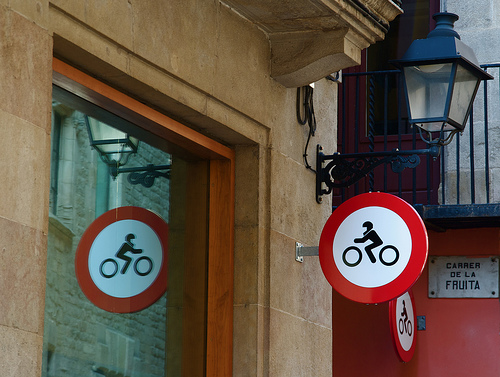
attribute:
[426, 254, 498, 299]
placard — white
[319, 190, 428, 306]
sign — white, reflective, red, circular, mounted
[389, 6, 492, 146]
light — off, reflective, iron, black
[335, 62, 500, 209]
railing — metal, iron, black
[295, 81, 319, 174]
wire — black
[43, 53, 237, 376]
window — wood, reflective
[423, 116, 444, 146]
bulb — white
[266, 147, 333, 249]
block — tan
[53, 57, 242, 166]
trim — wood, wooden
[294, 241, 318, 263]
bracket — grey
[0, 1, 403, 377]
building — orange, beige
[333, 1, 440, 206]
door — burgundy